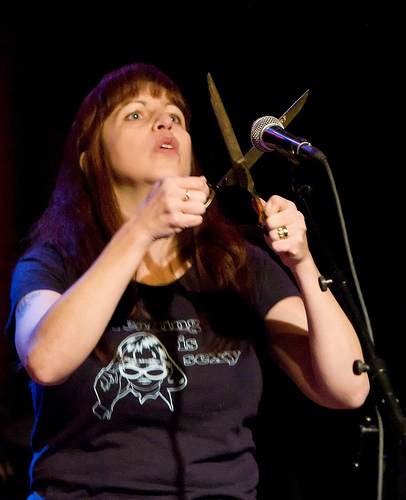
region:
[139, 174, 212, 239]
hand of a woman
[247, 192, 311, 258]
hand of a woman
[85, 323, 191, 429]
logo on a shirt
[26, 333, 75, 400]
elbow of a woman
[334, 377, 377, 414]
elbow of a woman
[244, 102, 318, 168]
black microphone on a stand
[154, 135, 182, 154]
mouth of a woman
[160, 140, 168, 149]
tooth of a woman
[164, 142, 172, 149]
tooth of a woman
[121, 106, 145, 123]
eye of a woman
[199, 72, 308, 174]
The blades of the shears.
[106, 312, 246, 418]
The graphic on the girl's shirt.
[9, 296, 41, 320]
The tattoo on the girl's left arm.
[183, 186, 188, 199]
The ring on the girl's middle finger.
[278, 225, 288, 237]
The rings on the girl's ring finger.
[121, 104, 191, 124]
The eyes of the girl.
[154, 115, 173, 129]
The nose of the girl.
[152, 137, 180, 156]
The lips of the girl.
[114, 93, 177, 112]
The eyebrows of the girl.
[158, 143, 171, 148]
The teeth in the lady's mouth.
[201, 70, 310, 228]
an open pair of scissors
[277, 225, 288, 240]
a set of wedding bands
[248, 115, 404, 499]
a microphone on a stand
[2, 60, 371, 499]
a woman looking upwards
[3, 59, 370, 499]
a woman holding a pair of scissors up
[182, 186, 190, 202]
a silver ring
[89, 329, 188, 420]
a line drawing of a girl in glasses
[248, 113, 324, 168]
a shiny blue microphone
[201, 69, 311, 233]
an unusually large pair of scissors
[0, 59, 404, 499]
a woman using a pair of scissors as she speaks into a microphone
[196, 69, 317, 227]
a large pair of scissors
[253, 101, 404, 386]
mic and stand with wire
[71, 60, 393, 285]
woman holding scissors in front of microphone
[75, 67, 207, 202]
light reflects off her eyes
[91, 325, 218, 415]
a graphic of a woman in glasses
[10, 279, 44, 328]
a tatto on the womans arm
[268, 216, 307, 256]
a ring on her finger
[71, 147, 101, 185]
her ear is coverd by hair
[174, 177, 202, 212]
a ring on her finger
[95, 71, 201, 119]
she has bangs on her hair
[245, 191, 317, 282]
woman is wearing rings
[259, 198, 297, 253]
woman is wearing rings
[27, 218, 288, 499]
the shirt is dark blue